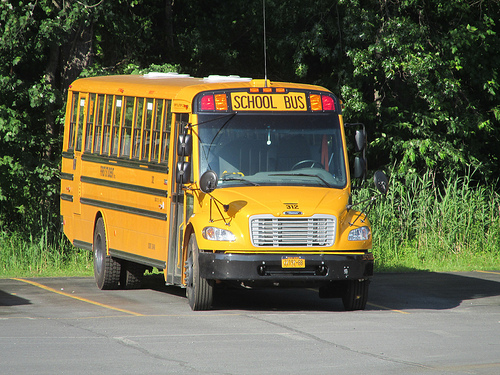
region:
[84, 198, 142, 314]
Tires on a bus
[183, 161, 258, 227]
Mirror on a bus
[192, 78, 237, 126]
Lights on a bus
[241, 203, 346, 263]
Grill on a bus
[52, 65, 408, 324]
Large, yellow school bus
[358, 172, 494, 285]
Tall green grass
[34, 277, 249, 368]
Gray paved parking lot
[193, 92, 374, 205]
Front windshield on a bus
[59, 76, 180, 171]
Small windows on a bus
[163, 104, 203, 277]
Door on a bus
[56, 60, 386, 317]
school bus on the road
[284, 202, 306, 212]
number 312 on the front of the bus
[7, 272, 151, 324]
yellow line on the road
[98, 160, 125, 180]
writing on the side of the bus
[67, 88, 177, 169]
row of windows on bus's passenger side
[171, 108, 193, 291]
door on bus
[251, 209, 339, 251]
bus's grill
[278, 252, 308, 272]
license plate on bus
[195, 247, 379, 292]
black front bumper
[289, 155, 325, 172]
steering wheel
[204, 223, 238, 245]
The left headlight of the bus.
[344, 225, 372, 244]
The right headlight of the bus.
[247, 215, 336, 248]
The gray grill on the front of the bus.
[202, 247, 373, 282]
The black fender of the bus.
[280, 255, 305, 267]
The yellow and blue license plate.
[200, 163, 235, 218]
The left side view mirror attached to the hood of the bus.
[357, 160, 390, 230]
The right side view mirror attached to the hood of the bus.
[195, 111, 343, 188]
The front windshield window of the bus.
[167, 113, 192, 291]
The door of the bus.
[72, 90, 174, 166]
The passenger windows of the bus.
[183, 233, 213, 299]
Tires on the school bus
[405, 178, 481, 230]
Green bushes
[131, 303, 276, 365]
The bus is on the road.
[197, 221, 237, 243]
Lights on the bus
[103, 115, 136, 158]
Windows on the bus.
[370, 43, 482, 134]
Green bushes.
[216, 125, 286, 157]
Windshield of the bus.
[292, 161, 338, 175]
Steering wheel on the bus.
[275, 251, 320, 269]
License plate of the bus.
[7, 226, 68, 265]
Green grass.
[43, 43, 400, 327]
a yellow school bus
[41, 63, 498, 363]
A bus parked in a parking lot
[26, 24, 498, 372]
A vacant school bus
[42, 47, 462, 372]
a handicap accessible school bus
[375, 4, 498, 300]
a thick grassy area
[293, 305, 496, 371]
hot steamy pavement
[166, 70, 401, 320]
full view mirrors for safety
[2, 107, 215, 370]
a school bus loading zone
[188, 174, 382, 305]
the front of a school bus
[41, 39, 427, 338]
a lonely school bus